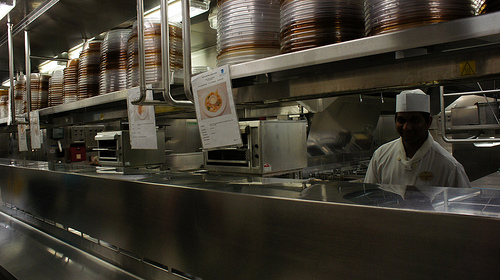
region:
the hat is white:
[390, 85, 436, 115]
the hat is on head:
[390, 87, 440, 160]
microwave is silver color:
[199, 112, 301, 172]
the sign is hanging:
[188, 70, 254, 152]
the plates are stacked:
[22, 29, 165, 91]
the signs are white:
[123, 65, 249, 151]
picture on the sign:
[196, 86, 235, 118]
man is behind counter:
[345, 90, 479, 227]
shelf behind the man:
[422, 85, 493, 140]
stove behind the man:
[317, 155, 411, 176]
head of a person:
[385, 73, 458, 136]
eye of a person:
[391, 104, 411, 125]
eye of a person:
[408, 108, 425, 133]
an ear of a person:
[422, 107, 444, 137]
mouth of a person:
[403, 131, 420, 136]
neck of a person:
[394, 138, 443, 155]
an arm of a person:
[345, 145, 397, 199]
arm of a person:
[445, 148, 466, 190]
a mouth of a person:
[403, 131, 420, 139]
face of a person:
[385, 108, 430, 142]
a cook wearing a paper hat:
[392, 93, 434, 145]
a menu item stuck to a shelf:
[188, 60, 248, 153]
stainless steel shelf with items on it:
[202, 0, 487, 65]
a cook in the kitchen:
[350, 80, 470, 196]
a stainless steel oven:
[87, 130, 163, 166]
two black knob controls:
[250, 137, 260, 163]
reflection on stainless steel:
[347, 180, 469, 215]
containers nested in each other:
[98, 29, 130, 95]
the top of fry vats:
[308, 153, 373, 182]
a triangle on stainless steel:
[457, 60, 482, 80]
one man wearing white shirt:
[363, 84, 462, 189]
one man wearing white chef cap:
[391, 84, 434, 144]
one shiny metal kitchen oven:
[203, 117, 311, 178]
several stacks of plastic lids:
[24, 19, 184, 104]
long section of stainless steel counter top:
[6, 142, 493, 270]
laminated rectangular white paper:
[187, 59, 250, 155]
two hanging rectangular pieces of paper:
[120, 63, 245, 155]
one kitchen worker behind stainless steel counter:
[358, 89, 483, 219]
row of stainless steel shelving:
[11, 0, 493, 128]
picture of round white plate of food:
[197, 79, 233, 120]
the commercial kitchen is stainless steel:
[6, 1, 499, 276]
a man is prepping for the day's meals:
[327, 78, 470, 229]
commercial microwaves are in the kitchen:
[89, 110, 309, 180]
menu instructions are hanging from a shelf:
[6, 69, 245, 174]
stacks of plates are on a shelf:
[2, 43, 408, 126]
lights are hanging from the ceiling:
[3, 3, 231, 65]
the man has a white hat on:
[391, 88, 433, 158]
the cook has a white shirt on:
[361, 132, 474, 197]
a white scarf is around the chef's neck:
[393, 128, 438, 173]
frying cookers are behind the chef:
[301, 156, 378, 190]